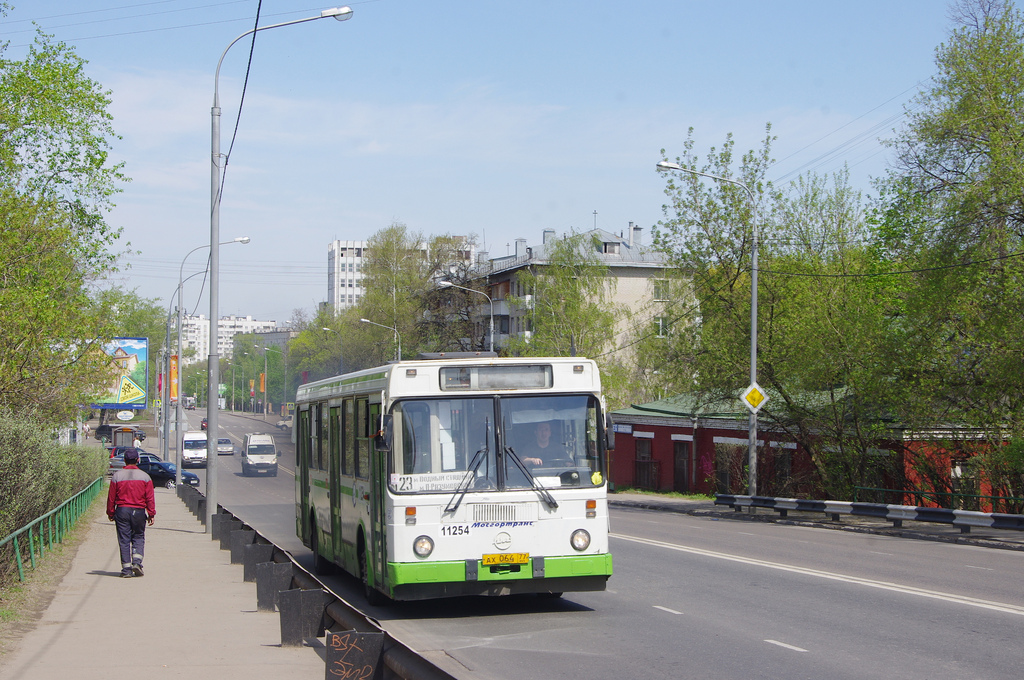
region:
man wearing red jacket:
[98, 440, 159, 574]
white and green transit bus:
[287, 326, 621, 614]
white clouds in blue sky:
[265, 123, 329, 168]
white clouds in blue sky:
[449, 69, 510, 111]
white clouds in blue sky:
[263, 180, 293, 216]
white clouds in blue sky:
[490, 110, 533, 159]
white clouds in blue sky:
[720, 40, 815, 135]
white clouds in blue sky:
[410, 4, 543, 100]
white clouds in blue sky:
[379, 83, 452, 153]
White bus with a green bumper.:
[285, 351, 619, 607]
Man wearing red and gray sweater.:
[106, 443, 157, 577]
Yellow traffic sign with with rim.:
[735, 377, 771, 415]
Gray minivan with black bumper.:
[241, 427, 284, 481]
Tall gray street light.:
[200, 3, 362, 542]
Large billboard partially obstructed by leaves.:
[29, 334, 157, 411]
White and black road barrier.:
[706, 486, 1021, 544]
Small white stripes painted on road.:
[648, 595, 816, 657]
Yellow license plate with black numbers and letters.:
[478, 549, 533, 568]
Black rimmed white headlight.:
[567, 527, 594, 553]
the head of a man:
[107, 434, 143, 474]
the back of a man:
[87, 445, 152, 540]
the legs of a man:
[98, 494, 178, 590]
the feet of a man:
[94, 533, 168, 607]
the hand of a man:
[133, 489, 190, 531]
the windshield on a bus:
[375, 371, 682, 515]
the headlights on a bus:
[375, 492, 619, 584]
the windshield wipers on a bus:
[411, 423, 561, 535]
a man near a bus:
[46, 372, 424, 597]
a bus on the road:
[275, 336, 772, 654]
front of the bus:
[335, 342, 664, 590]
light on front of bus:
[370, 516, 487, 587]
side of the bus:
[249, 392, 412, 555]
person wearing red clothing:
[63, 426, 194, 570]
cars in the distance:
[174, 389, 296, 487]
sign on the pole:
[697, 301, 846, 464]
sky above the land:
[340, 20, 648, 156]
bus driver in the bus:
[457, 329, 629, 504]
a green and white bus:
[276, 333, 665, 659]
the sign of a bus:
[422, 353, 550, 398]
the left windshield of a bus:
[364, 390, 492, 495]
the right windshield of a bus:
[500, 393, 608, 486]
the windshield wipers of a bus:
[438, 437, 559, 517]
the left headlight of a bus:
[414, 527, 452, 563]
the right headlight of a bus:
[557, 517, 609, 562]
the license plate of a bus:
[473, 542, 538, 577]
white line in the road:
[640, 589, 710, 637]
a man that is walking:
[92, 445, 175, 572]